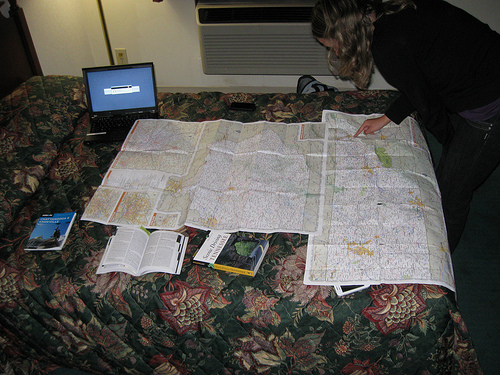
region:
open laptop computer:
[77, 61, 159, 143]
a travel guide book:
[22, 209, 77, 253]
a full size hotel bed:
[0, 0, 485, 373]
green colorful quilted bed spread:
[0, 72, 483, 373]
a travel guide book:
[190, 228, 270, 278]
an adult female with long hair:
[309, 0, 499, 254]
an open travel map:
[78, 119, 330, 237]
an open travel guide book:
[93, 223, 191, 275]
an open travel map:
[300, 107, 456, 299]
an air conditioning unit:
[193, 3, 343, 75]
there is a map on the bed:
[183, 118, 423, 246]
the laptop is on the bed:
[80, 76, 171, 130]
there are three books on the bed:
[28, 209, 255, 284]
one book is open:
[103, 221, 184, 282]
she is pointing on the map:
[346, 119, 376, 149]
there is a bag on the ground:
[289, 68, 341, 99]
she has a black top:
[383, 1, 492, 118]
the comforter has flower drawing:
[105, 287, 395, 342]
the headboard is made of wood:
[2, 12, 57, 87]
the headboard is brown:
[6, 12, 51, 68]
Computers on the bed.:
[37, 39, 206, 176]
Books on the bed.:
[90, 200, 307, 294]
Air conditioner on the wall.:
[192, 0, 386, 99]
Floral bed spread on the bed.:
[28, 122, 479, 363]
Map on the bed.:
[81, 107, 353, 276]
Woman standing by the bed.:
[302, 7, 493, 231]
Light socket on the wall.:
[93, 13, 160, 93]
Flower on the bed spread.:
[148, 278, 237, 355]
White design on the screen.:
[96, 79, 175, 131]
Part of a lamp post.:
[92, 1, 143, 90]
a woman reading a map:
[304, 7, 489, 211]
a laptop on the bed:
[73, 63, 168, 135]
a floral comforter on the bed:
[166, 283, 313, 356]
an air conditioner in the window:
[194, 6, 312, 79]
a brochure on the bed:
[21, 203, 78, 254]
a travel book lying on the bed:
[192, 226, 264, 286]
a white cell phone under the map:
[332, 281, 374, 298]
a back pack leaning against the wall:
[295, 77, 342, 93]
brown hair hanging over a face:
[324, 10, 386, 82]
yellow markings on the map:
[340, 226, 379, 264]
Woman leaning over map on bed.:
[312, 1, 497, 258]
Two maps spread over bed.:
[83, 108, 473, 295]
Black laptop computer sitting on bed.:
[70, 59, 171, 156]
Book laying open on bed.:
[84, 224, 190, 290]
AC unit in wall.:
[185, 6, 350, 78]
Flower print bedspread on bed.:
[18, 92, 73, 193]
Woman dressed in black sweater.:
[371, 0, 498, 152]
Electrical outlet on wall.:
[108, 42, 136, 66]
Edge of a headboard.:
[1, 0, 53, 90]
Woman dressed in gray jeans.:
[436, 101, 494, 266]